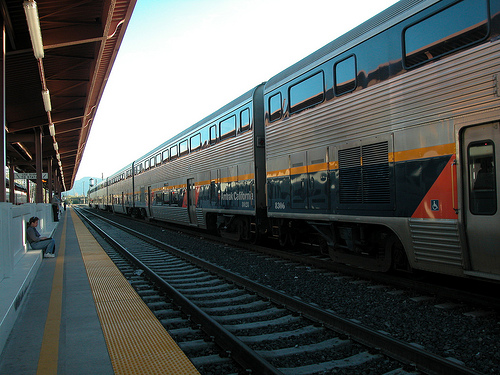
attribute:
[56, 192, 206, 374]
paint — yellow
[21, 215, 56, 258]
man — sitting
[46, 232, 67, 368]
line — yellow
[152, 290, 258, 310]
tie — CONCRETE 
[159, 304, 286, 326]
tie — CONCRETE 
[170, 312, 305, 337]
tie — CONCRETE 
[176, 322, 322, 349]
tie — CONCRETE 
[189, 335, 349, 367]
tie — CONCRETE 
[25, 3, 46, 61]
lights — white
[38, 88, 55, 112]
light — white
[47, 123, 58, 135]
light — white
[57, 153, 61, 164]
light — white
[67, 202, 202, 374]
line — yellow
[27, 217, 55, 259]
person — sitting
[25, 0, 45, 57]
light — tube, fluorescent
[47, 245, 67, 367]
line — painted, yellow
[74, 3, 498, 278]
train — large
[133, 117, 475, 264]
train — silver, orange, blue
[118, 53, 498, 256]
train — silver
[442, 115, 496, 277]
doors — metal